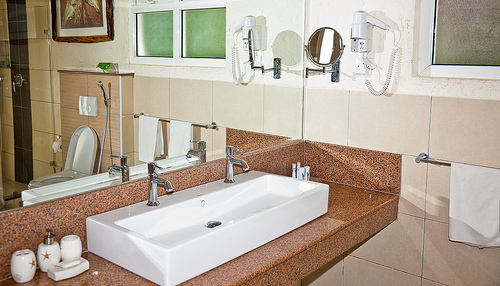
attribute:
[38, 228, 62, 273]
dispenser — gold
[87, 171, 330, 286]
sink — white, chrome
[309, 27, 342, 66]
mirror — small, round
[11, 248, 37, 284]
holder — white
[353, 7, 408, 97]
hair dryer — white, small, hair dryer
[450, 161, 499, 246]
towel — white, open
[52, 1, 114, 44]
frame — wood, black, white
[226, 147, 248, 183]
faucet — silver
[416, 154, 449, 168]
rack — silver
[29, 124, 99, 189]
toilet — white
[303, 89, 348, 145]
tile — tan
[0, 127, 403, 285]
counter top — brown